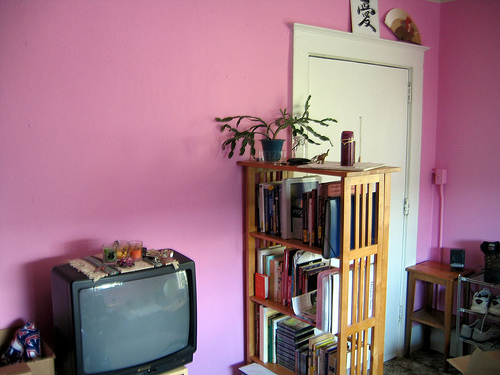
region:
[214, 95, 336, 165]
the plant on the shelf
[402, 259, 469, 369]
the small table near the door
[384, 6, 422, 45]
the fan above the door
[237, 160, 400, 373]
the bookshelf near thedoor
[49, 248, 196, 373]
the box shaped television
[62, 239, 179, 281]
the clutter on the television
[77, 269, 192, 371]
the glare on the television screen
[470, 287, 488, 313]
the shoe on the rack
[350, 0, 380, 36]
the white paper with Asian writing on it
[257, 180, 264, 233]
the book on the shelf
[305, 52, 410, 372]
White door on the wall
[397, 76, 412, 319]
Hinges on the door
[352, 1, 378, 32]
Chinese character on the top of the door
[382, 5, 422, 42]
Fan next to the Chinese character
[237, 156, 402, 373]
Shelf in the room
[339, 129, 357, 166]
Bottle on the top of the shelf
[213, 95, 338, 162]
Pot plant on the top of the shelf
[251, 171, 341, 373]
Books on the shelf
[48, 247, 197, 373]
TV in the room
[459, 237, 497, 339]
Shoes on the shoe rack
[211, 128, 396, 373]
A bookcase located next to a doorway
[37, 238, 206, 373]
A television set against a pink wall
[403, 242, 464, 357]
A night stand placed next to a door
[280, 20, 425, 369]
A white door against a pink wall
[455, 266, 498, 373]
A shoe rack next to the night stand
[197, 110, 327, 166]
A plant on top of the bookcase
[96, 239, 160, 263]
Three candles placed on top of a tv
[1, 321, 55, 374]
A box filled with stuff next to a television set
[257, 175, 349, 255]
A collection of books on the top shelf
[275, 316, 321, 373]
A collection of DVDs on the bottom shelf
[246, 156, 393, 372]
a book shelf with books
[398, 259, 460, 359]
a brown stand by a door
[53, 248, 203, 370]
a black tv by a wall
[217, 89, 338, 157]
a plaint in a flower pot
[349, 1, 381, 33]
a white sign over a door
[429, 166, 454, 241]
a pink metal pipe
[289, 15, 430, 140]
a white door with a white frame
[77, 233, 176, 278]
candles on a tv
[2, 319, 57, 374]
a brown box with stuff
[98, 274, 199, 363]
a reflection in a tv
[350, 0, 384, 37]
Chinese character above door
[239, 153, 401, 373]
light brown wooden bookcase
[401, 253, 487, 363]
wooden end table in corner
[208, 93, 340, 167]
green plant on wooden bookcase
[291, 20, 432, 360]
white door with white frame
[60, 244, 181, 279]
white cloth on top of TV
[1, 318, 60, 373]
blue art piece in brown box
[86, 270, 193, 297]
light glare on TV screen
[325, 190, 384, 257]
blue folder at end of shelf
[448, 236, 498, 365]
three rows of shoes